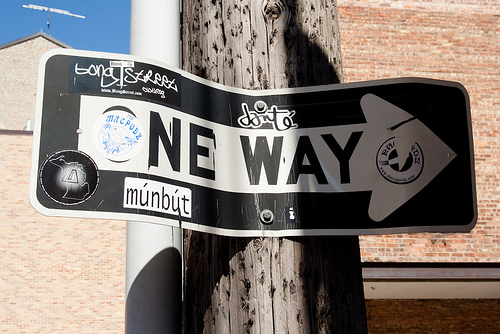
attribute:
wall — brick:
[369, 9, 490, 147]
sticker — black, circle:
[40, 148, 103, 206]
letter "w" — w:
[235, 132, 285, 187]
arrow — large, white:
[32, 47, 480, 226]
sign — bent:
[122, 80, 372, 213]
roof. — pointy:
[10, 19, 104, 80]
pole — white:
[123, 0, 181, 331]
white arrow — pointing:
[66, 86, 464, 237]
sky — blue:
[72, 15, 114, 39]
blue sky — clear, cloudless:
[0, 1, 132, 53]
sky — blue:
[0, 0, 134, 57]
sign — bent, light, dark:
[10, 44, 487, 246]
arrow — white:
[68, 87, 465, 226]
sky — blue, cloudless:
[0, 1, 131, 63]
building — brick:
[337, 9, 497, 331]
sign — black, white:
[35, 20, 477, 261]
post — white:
[125, 1, 184, 331]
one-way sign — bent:
[28, 47, 478, 237]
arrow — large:
[93, 131, 450, 184]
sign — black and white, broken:
[30, 48, 480, 237]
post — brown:
[179, 4, 348, 331]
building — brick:
[8, 24, 124, 331]